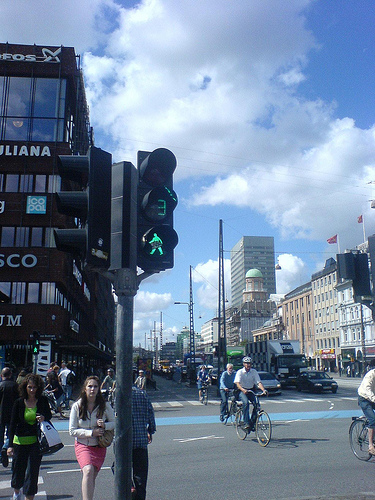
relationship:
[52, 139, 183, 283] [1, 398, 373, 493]
street light near street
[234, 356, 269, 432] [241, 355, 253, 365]
man wearing cap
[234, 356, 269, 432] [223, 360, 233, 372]
man with hair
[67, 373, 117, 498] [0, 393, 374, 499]
woman on street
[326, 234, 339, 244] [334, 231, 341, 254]
flag on pole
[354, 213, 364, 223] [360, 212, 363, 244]
flag on pole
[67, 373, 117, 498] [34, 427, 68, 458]
woman with bag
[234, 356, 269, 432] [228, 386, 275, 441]
man wearing pants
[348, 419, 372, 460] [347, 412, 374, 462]
tire on bike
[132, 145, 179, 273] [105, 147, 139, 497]
traffic light on pole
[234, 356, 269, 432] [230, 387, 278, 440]
man on bicycle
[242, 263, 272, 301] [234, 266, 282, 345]
dome on building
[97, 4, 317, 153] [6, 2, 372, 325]
cloud in sky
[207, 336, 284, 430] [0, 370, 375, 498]
cars on street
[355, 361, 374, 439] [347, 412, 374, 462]
person riding bike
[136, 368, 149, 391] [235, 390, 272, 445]
person riding bicycle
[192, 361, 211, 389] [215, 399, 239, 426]
person riding bike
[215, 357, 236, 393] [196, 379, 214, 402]
person riding bike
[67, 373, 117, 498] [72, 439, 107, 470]
woman wearing pink skirt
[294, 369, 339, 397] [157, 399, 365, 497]
car on street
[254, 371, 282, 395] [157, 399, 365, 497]
car on street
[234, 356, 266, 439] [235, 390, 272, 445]
man on bicycle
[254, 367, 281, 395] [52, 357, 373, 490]
car about to cross street